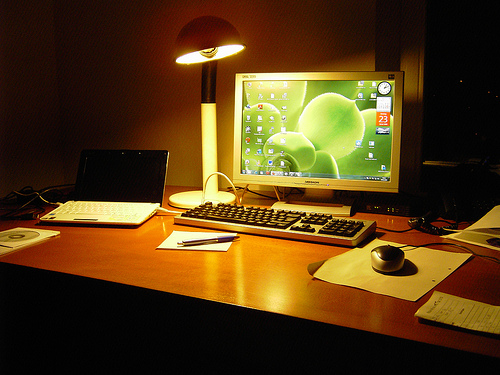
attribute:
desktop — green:
[241, 81, 393, 180]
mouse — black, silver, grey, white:
[372, 245, 403, 268]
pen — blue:
[179, 240, 239, 247]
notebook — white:
[162, 230, 233, 256]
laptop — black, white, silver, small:
[47, 150, 174, 226]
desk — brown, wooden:
[3, 190, 499, 348]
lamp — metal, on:
[181, 22, 234, 205]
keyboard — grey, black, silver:
[190, 202, 378, 241]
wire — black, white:
[162, 181, 245, 212]